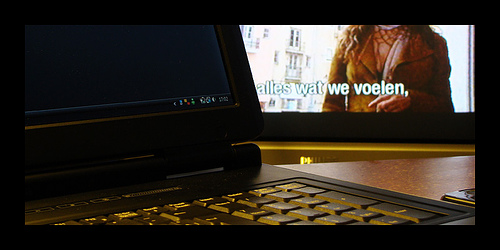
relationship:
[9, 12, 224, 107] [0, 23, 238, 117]
screen on screen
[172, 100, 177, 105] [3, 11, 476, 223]
icon on computer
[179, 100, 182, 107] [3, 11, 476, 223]
icon on computer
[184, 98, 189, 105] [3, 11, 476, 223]
icon on computer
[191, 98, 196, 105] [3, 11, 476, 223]
icon on computer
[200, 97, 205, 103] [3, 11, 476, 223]
icon on computer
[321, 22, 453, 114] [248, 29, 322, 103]
woman in front of building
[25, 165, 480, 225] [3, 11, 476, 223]
keypad for computer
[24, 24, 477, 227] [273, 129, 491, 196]
laptop open on table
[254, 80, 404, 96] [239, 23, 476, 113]
words on screen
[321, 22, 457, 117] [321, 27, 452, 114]
woman with jacket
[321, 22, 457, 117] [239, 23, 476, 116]
woman on screen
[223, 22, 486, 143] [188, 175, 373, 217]
tv shining on keyboard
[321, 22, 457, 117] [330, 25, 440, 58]
woman with brown hair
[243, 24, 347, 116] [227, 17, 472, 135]
buildings on tv screen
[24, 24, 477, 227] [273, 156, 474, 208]
laptop on countertop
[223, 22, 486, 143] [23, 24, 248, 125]
tv behind screen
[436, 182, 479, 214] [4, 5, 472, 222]
book near laptop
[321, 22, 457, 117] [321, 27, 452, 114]
woman wears jacket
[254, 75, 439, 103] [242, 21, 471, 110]
words on screen